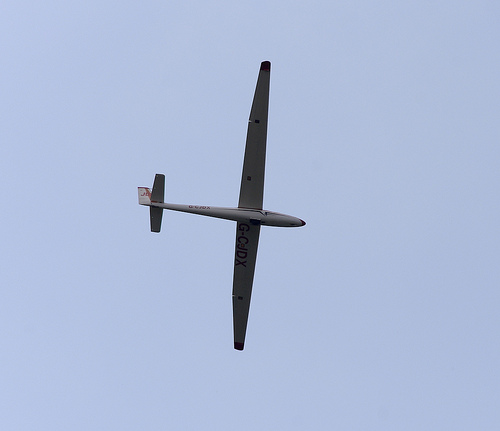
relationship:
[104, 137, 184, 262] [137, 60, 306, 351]
backend of glider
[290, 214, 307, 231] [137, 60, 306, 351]
nose of glider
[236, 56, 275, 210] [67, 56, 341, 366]
wing of plane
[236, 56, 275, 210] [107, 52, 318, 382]
wing of plane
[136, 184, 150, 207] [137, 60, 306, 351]
stabilizer on glider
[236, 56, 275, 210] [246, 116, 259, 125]
wing with steering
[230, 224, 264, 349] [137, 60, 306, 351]
wing on glider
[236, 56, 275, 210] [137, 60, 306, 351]
wing on glider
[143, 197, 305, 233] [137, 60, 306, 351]
underside of glider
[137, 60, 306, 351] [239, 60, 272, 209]
glider has wing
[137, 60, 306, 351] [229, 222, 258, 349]
glider has wing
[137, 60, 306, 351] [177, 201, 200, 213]
glider on writing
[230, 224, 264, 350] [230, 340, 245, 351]
wing has tip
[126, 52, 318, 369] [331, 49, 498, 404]
glider in sky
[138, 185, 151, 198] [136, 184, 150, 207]
markings on stabilizer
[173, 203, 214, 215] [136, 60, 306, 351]
writing on glider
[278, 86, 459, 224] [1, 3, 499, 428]
clouds in sky